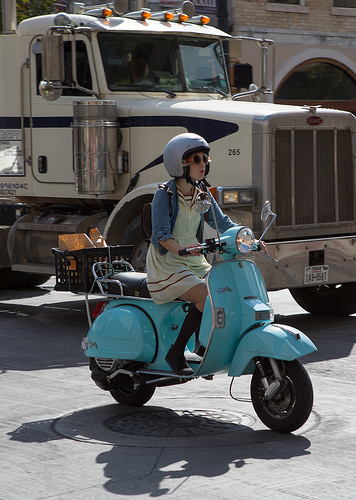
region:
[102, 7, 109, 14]
an orange caution light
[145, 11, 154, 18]
an orange caution light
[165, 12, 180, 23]
an orange caution light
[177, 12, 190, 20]
an orange caution light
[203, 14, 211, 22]
an orange caution light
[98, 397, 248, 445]
a large man hole cover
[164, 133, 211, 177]
a gray helmet on head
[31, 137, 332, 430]
a girl riding a blue scooter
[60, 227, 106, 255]
brown paper sacks in a black crate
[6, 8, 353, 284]
a huge semi truck driving next to the girl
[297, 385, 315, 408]
front tire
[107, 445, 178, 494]
a shadow on the ground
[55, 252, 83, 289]
a black basket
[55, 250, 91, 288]
the basket on the moped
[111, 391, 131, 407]
the tire on the moped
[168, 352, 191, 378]
the womens shoe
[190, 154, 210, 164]
sunglasses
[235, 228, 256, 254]
headlight on the moped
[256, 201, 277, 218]
a mirror on the moped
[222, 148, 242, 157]
numbers on the truck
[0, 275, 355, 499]
a road made of concrete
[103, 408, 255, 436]
a manhole cover in the road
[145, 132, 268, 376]
a girl driving a scooter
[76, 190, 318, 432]
a blue scooter in the road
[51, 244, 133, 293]
a black basket on the scooter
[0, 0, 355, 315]
a large truck in the road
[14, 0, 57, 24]
a green tree in the background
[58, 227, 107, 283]
a group of paper bags in the basket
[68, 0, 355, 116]
a building in the background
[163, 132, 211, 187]
the girl's helmet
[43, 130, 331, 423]
person riding motorized bike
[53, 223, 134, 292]
basket with items on bike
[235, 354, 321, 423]
front tire of bike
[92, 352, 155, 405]
rear tire of bike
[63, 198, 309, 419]
motorized bike on street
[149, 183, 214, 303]
dress on person on bike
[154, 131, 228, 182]
helmet on person on bike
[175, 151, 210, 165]
sunglasses on bike rider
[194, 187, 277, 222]
mirrors on motorized bike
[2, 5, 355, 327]
truck next to bike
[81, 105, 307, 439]
the woman is on a scooter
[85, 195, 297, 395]
the scooter is blue in color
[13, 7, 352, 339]
a semi is next to the scooter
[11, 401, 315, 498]
the woman and her scooter are casting a shadow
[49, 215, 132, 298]
the woman has a black basket tied to her scooter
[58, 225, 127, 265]
the basket has brown paper bags in it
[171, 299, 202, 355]
the woman is wearing black socks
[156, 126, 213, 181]
the woman wears a helmet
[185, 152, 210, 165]
the woman is wearing sunglasses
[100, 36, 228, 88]
the semi trucks windshield